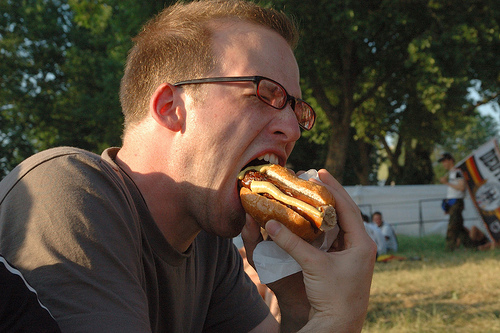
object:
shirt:
[0, 145, 270, 332]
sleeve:
[4, 153, 152, 333]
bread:
[260, 162, 335, 208]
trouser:
[439, 199, 474, 250]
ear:
[146, 81, 182, 131]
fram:
[173, 73, 252, 86]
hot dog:
[240, 163, 337, 245]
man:
[0, 0, 374, 333]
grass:
[352, 232, 500, 332]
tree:
[0, 0, 500, 185]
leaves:
[386, 62, 394, 72]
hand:
[264, 168, 376, 312]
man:
[440, 152, 477, 251]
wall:
[342, 185, 454, 238]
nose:
[265, 105, 303, 144]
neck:
[113, 145, 204, 250]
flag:
[451, 134, 499, 246]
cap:
[434, 151, 457, 163]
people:
[370, 210, 398, 256]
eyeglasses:
[171, 75, 318, 131]